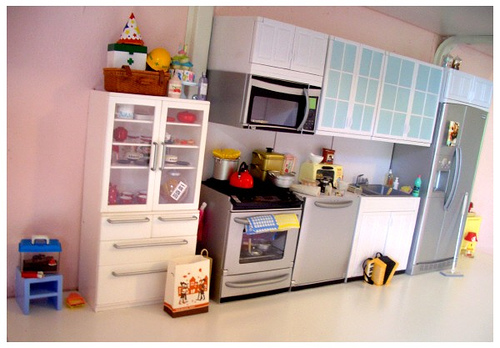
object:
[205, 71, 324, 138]
microwave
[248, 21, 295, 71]
cabinet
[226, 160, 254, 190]
tea kettle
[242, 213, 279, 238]
towel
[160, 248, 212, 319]
bag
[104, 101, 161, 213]
cabinet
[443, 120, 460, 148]
picture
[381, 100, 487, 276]
refrigerator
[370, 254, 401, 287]
case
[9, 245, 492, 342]
floor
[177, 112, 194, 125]
bowl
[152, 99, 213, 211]
cabinet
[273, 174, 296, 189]
pot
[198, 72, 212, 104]
bottle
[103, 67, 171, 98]
basket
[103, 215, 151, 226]
handle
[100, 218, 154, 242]
drawer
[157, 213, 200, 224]
handle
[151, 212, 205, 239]
drawer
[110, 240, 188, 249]
handle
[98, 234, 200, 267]
drawer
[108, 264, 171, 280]
handle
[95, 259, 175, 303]
drawer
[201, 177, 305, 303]
oven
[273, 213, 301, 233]
towel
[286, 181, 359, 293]
dishwasher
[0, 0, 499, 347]
kitchen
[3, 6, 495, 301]
wall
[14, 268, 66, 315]
stool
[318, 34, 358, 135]
cabinets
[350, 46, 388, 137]
door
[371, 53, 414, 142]
door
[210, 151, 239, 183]
pot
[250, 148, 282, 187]
pot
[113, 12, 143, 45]
party hat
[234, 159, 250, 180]
handle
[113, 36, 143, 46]
stars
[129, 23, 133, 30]
dots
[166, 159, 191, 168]
dishes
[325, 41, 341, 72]
square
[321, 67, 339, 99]
square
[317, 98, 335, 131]
square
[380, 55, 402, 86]
square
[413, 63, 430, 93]
square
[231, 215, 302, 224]
handle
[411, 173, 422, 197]
bottle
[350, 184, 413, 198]
sink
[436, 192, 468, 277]
mop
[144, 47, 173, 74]
hard hat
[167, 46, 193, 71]
toy